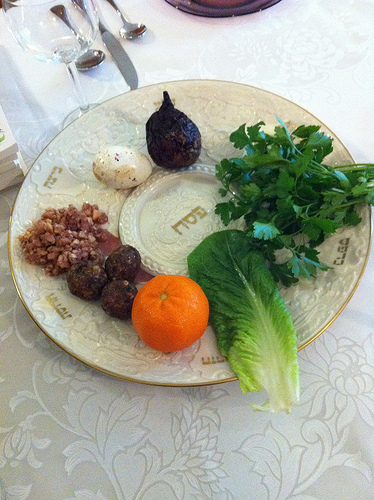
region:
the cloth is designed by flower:
[125, 425, 226, 485]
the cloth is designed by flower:
[202, 463, 215, 471]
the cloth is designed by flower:
[108, 411, 186, 476]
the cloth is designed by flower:
[161, 422, 286, 498]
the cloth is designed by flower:
[150, 428, 189, 469]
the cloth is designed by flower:
[110, 374, 224, 480]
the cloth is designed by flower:
[165, 374, 280, 481]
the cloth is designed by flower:
[124, 353, 195, 427]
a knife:
[84, 19, 154, 127]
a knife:
[92, 16, 199, 144]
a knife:
[99, 5, 155, 95]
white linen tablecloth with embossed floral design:
[71, 403, 338, 479]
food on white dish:
[23, 99, 337, 354]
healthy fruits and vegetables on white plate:
[43, 112, 332, 309]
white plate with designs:
[41, 313, 121, 379]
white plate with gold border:
[310, 262, 354, 349]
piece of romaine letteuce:
[203, 229, 309, 405]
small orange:
[130, 270, 212, 351]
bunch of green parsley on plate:
[209, 118, 359, 264]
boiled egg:
[82, 139, 154, 191]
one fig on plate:
[141, 90, 202, 168]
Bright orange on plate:
[142, 276, 215, 344]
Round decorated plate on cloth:
[23, 104, 368, 367]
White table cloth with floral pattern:
[36, 392, 372, 468]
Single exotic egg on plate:
[73, 144, 147, 191]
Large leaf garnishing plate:
[202, 237, 312, 429]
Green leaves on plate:
[230, 121, 373, 243]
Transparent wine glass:
[20, 4, 103, 114]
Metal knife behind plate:
[79, 9, 174, 127]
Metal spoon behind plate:
[109, 3, 159, 43]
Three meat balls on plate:
[75, 251, 155, 318]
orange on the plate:
[117, 264, 201, 362]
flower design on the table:
[61, 410, 186, 486]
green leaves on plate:
[246, 129, 336, 240]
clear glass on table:
[44, 32, 91, 72]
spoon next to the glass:
[80, 33, 117, 78]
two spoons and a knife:
[73, 19, 157, 94]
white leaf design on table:
[90, 393, 157, 467]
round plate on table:
[30, 90, 96, 197]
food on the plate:
[54, 100, 319, 343]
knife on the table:
[102, 52, 151, 100]